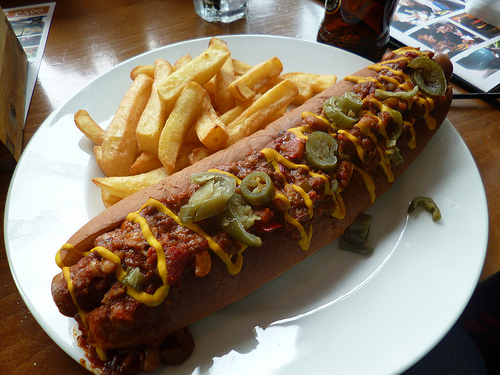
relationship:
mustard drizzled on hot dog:
[127, 213, 177, 295] [49, 51, 454, 318]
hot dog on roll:
[26, 25, 468, 340] [47, 46, 460, 355]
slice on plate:
[405, 190, 443, 230] [13, 23, 494, 373]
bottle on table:
[306, 0, 412, 65] [8, 2, 499, 374]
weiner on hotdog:
[49, 49, 452, 314] [45, 46, 457, 351]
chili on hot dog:
[77, 242, 187, 309] [51, 34, 458, 372]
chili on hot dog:
[193, 155, 334, 235] [51, 34, 458, 372]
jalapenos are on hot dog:
[303, 129, 341, 174] [51, 46, 452, 351]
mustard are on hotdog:
[127, 213, 177, 295] [45, 46, 457, 351]